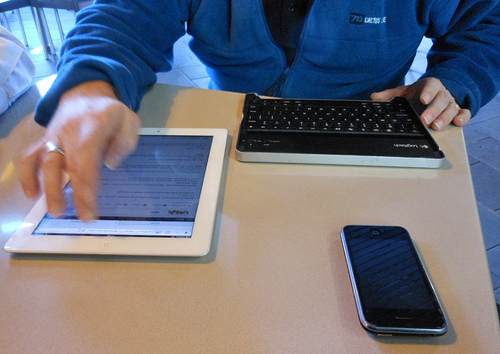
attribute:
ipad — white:
[4, 107, 229, 258]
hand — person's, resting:
[371, 63, 475, 151]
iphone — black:
[340, 203, 461, 350]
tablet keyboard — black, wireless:
[239, 86, 459, 176]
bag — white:
[0, 34, 53, 131]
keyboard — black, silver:
[209, 74, 486, 196]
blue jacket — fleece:
[34, 1, 499, 124]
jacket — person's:
[51, 13, 498, 101]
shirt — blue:
[115, 2, 463, 89]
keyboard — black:
[238, 85, 451, 176]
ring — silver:
[39, 136, 56, 153]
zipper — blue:
[250, 3, 337, 107]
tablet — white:
[3, 124, 228, 264]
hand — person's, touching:
[16, 80, 138, 222]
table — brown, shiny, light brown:
[0, 65, 499, 352]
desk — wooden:
[0, 83, 500, 350]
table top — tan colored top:
[0, 262, 356, 352]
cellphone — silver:
[340, 219, 460, 343]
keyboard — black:
[228, 87, 445, 171]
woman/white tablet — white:
[4, 95, 231, 265]